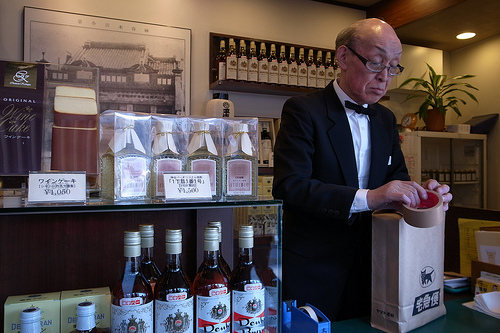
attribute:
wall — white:
[177, 8, 308, 30]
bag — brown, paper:
[367, 200, 452, 331]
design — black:
[413, 290, 440, 315]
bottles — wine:
[103, 213, 311, 328]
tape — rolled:
[401, 187, 443, 228]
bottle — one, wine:
[233, 222, 274, 329]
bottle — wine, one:
[194, 223, 233, 330]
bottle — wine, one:
[154, 225, 197, 332]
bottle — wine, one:
[112, 226, 157, 331]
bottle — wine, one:
[99, 108, 254, 194]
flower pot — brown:
[420, 107, 450, 129]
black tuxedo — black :
[302, 107, 408, 155]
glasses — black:
[332, 37, 399, 75]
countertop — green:
[332, 291, 499, 331]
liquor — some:
[99, 111, 151, 203]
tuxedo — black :
[267, 82, 409, 327]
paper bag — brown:
[366, 210, 446, 331]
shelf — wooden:
[210, 67, 330, 97]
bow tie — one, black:
[343, 98, 371, 115]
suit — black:
[277, 87, 410, 312]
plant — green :
[396, 60, 478, 135]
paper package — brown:
[368, 209, 446, 331]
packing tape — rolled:
[404, 185, 449, 230]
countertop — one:
[344, 308, 490, 331]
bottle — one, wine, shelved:
[156, 225, 193, 331]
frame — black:
[340, 43, 405, 80]